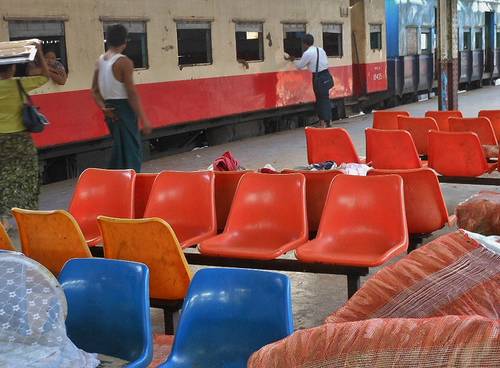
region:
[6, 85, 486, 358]
A sitting area in a train station.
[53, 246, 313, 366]
Two blue chairs.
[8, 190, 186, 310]
Two orange chairs on a black frame.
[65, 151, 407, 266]
A row of 4 red chairs.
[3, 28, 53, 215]
A woman carrying something on her head.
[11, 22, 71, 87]
A person leaned out the train window.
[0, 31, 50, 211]
Woman with a black pocket book over her shoulder.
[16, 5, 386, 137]
A red and white train car.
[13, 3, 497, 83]
Passenger windows on the train cars.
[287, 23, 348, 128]
Man dressed in a long sleeved white shirt.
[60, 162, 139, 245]
orange seat at a train station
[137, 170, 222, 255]
orange seat at a train station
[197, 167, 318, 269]
orange seat at a train station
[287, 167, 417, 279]
orange seat at a train station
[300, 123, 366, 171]
orange seat at a train station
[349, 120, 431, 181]
orange seat at a train station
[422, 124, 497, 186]
orange seat at a train station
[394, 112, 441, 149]
orange seat at a train station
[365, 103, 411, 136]
orange seat at a train station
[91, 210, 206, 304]
orange seat at a train station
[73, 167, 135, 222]
that is a chair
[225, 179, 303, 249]
that is a chair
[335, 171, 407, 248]
that is a chair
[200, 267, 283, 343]
that is a chair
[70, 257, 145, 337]
that is a chair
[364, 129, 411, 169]
that is a chair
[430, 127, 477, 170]
that is a chair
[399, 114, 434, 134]
that is a chair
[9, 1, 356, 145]
People walking in front of the train.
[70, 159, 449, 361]
The train waiting area.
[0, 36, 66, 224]
A woman carrying something.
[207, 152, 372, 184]
A pile of clothes on the seats.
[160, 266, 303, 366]
A blue seat in the waiting area.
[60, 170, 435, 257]
Four seats in the waiting area.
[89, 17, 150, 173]
A man looking at the train.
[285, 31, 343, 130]
A man talking to someone in the train.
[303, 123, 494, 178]
Three orange seats in the waiting area.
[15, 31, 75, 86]
A person looking out the train window.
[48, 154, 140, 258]
The chair is orange.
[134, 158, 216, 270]
The chair is orange.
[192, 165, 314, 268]
The chair is orange.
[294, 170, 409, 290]
The chair is orange.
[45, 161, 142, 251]
The chair is unoccupied.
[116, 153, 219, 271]
The chair is unoccupied.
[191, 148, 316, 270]
The chair is unoccupied.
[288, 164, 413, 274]
The chair is unoccupied.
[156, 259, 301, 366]
The chair is unoccupied.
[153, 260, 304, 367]
The chair is blue.